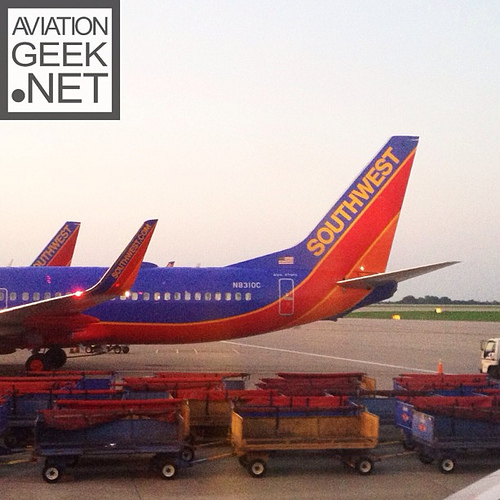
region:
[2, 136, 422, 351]
southwest airplane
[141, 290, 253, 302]
airplane windows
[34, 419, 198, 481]
side of a black suv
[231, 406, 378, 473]
wooden luggage cart with wheels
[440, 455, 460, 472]
black wheel with white rim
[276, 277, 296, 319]
closed door of airplane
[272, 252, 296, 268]
American flag on side of plane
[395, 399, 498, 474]
blue luggage cart with wheels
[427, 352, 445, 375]
orange cone on the runway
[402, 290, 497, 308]
trees on the side of the runway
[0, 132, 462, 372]
A huge airplane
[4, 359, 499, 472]
A lot of blue wagons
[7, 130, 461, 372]
The airplane has tail fins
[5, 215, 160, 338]
The airplane's wings tip up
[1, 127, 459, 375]
The airplane has a door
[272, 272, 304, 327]
The door is small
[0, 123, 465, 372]
The airplane has an american flag on it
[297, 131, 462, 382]
The tailfin has a large word on it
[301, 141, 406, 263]
The word is yellow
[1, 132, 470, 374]
The airplane has a number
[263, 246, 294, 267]
The American flag.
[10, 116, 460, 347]
A jet airliner.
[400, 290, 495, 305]
Forest in the distance.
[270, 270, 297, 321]
One of the airplane's doors.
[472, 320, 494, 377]
A white truck.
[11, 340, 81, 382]
The landing gear is down.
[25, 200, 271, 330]
The planes wings bend upward.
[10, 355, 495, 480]
Dollies for loading and unloading the plane.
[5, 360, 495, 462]
Several dollies of different colors.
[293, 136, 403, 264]
The airline's name is written on the vertical stabilizer.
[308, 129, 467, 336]
Tail section of an airplane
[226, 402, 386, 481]
Luggage cart on a tarmac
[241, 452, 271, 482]
wheels on a cart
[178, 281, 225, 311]
windows on an airplane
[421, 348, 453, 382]
traffic cone on a runway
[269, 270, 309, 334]
rear door on an airplane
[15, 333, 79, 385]
wheels of an airplane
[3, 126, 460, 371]
airplane at an airport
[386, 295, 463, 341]
runway markers at an airport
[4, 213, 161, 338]
wing of an airplane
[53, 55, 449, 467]
planes and vehicles on tarmac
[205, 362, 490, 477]
yellow blue and red open carts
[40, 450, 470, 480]
small black and white wheels on carts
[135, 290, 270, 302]
row of passenger windows on plane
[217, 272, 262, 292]
identification number on plane over windows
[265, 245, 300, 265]
U.S. flag over plane door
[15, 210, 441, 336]
planes painted orange and blue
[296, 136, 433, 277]
airplane tail with name of airline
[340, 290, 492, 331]
strip of green grass on airfield